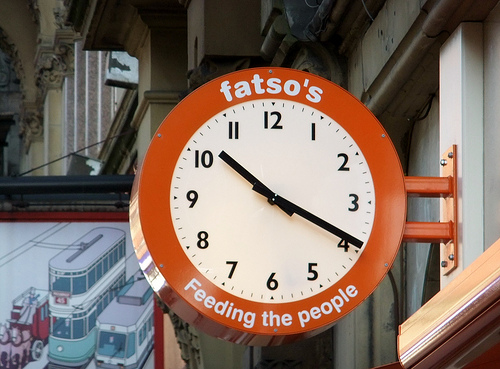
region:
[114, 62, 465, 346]
a clock attached to a wall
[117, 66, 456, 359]
the clock is orange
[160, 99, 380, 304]
the clock face is white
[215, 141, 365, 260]
the clock hands are black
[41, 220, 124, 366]
a drawing of a double-decker bus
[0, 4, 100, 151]
detailing on the wall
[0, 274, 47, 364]
a horse and carriage by the bus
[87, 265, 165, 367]
a train by the bus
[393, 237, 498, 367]
a ledge by the clock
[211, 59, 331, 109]
a store name on the clock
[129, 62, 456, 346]
clock attached to building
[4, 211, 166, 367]
picture in red frame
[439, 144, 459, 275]
four bolts on metal plate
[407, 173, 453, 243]
two poles on plate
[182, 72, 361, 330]
white words on clock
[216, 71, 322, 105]
words arranged in a curve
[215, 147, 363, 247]
black hands of clock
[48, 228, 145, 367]
illustration of city vehicles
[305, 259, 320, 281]
black number on clock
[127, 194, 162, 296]
light reflection on clock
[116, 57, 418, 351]
fatso's fat round orange clock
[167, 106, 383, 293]
it's 10:19am in the world of fatso's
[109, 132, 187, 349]
glare or reflection on the left side of fatso's clock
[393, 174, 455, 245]
to the right, an orange bracket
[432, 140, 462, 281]
bracket bolted w/ four big silvertone bolts attach fatso's clock to fatso's wall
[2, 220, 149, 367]
several modes of transportation painted or drawn on the wall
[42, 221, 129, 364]
blue stylized doubledecker bus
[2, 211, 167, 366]
a red frame around the multiple transportation vehicles picture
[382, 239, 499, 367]
wooden ledge beneath window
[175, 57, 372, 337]
'fatso's feeding the people'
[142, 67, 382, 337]
clock is round and big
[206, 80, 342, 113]
name on clock in white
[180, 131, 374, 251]
hands and numbers in black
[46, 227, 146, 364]
two buses drawn below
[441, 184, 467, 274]
clock on the hinges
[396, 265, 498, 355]
board where window is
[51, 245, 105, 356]
two tiered bus in picture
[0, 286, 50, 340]
red wagon beside bus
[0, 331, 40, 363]
two horses carrying truck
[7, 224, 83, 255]
wires from the bus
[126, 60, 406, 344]
One large orange clock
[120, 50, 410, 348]
One large orange clock with white background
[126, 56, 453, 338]
One large orange clock attached to wall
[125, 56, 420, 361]
One large orange clock attached to wall have back writing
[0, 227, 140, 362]
Three types of transportation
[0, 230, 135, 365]
Three types of transportation on background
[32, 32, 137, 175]
Tan columns in background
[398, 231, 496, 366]
Wooden side trim on building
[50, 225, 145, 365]
Picture of automobile transportation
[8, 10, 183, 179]
Columns in background